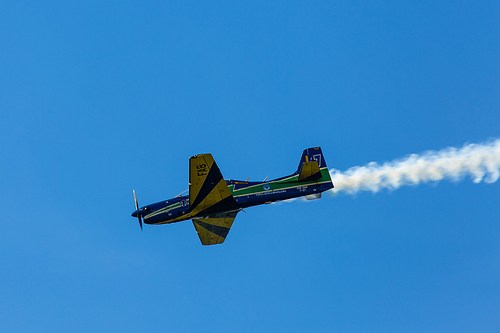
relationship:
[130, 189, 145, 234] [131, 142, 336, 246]
propeller on airplane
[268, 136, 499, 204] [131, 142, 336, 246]
smoke trail from airplane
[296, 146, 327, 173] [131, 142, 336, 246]
tail fin on airplane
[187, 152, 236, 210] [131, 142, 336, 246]
wing on airplane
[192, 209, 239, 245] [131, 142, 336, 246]
wing on airplane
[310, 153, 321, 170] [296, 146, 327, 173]
7 on tail fin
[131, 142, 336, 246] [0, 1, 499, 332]
airplane in sky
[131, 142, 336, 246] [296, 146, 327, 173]
airplane has a tail fin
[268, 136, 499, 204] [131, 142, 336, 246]
smoke trail coming from airplane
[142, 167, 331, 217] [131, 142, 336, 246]
stripe on airplane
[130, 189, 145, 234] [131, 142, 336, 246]
propeller at front of airplane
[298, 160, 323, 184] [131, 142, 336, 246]
tail wing on airplane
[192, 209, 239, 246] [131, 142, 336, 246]
right wing on airplane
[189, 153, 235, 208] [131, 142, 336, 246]
left wing on airplane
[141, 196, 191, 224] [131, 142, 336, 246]
front end of airplane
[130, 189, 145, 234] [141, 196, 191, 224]
propeller on front end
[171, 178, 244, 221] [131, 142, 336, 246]
cockpit of airplane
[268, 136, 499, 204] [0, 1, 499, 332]
smoke trail in sky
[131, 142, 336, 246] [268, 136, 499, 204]
airplane leaving behind a smoke trail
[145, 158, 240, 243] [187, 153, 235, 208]
stripe under left wing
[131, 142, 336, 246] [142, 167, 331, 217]
airplane has a stripe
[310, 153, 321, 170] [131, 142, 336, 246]
7 on airplane